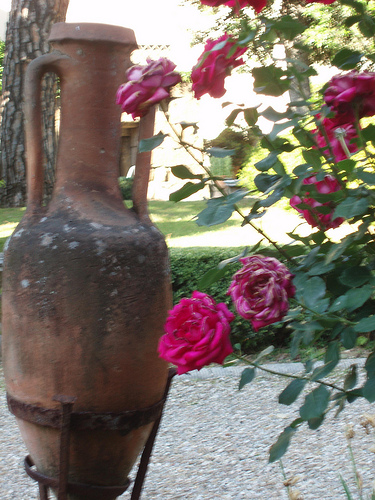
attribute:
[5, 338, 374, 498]
gravel — gray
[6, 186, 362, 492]
ground — green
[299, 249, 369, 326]
leaf — green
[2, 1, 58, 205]
trunk — brown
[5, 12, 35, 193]
tree bark — brown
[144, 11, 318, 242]
sunlight — bright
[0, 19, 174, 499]
pot — brown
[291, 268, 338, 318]
leaf — green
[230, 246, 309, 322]
rose — faded, dying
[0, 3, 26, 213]
tree trunk — very large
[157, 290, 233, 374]
rose — pink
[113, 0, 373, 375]
roses — dark pink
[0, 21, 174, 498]
vase — brown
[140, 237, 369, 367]
bush — green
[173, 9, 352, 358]
flowers — pink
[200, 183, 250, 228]
leaves — green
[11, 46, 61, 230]
handle — brown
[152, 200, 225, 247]
grass — green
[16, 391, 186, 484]
base — metal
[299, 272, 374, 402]
shrubbery — green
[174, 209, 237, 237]
grass — green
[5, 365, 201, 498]
pot holder — steel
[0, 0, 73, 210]
trunk — brown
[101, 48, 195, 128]
flower — pink, wilting